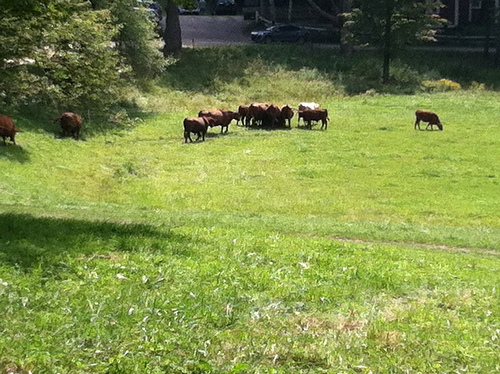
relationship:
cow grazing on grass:
[411, 105, 447, 135] [2, 89, 497, 371]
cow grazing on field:
[175, 89, 337, 157] [2, 0, 499, 371]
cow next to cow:
[301, 109, 322, 126] [297, 96, 324, 107]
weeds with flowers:
[162, 45, 499, 95] [406, 69, 476, 104]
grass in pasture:
[2, 45, 496, 372] [13, 50, 498, 372]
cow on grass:
[409, 106, 446, 133] [360, 86, 499, 188]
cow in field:
[409, 107, 444, 127] [28, 102, 480, 357]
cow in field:
[57, 109, 92, 139] [1, 51, 499, 371]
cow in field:
[409, 107, 444, 127] [2, 0, 499, 371]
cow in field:
[198, 109, 240, 131] [1, 51, 499, 371]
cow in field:
[297, 105, 337, 128] [1, 51, 499, 371]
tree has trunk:
[345, 0, 442, 90] [381, 5, 387, 95]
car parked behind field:
[247, 23, 327, 44] [5, 102, 492, 365]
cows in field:
[183, 102, 329, 145] [1, 51, 499, 371]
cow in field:
[414, 106, 441, 131] [213, 143, 463, 270]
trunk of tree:
[374, 11, 397, 86] [342, 0, 445, 81]